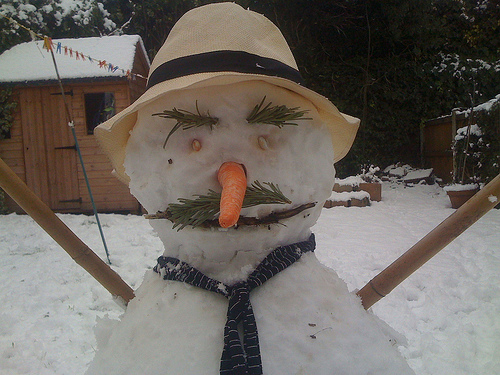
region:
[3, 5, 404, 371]
a snowman wearing a hat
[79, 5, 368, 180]
a beige straw hat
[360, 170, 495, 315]
a stick on right side of snowman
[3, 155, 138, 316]
a stick on left side of snowman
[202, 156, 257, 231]
a carrot forming the nose of snowman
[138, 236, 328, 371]
a black tie of snowman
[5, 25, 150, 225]
a building cover with snow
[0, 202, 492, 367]
a filed covered with snow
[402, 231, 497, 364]
footsteps over the snow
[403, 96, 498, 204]
a fence of wood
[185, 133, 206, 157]
the eye of a snowman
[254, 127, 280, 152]
the eye of a snowman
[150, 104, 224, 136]
the eyebrows of a snowman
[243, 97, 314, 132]
the eyebrows of a snowman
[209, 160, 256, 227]
a carrot nose of a snowman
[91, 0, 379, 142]
the hat of a snowman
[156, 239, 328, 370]
a tie on a snowman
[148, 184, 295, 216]
the mustache of a snowman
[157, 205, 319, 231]
the mouth of a snowman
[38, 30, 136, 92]
the roof of a building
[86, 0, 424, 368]
a snowman in the snow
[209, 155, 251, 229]
a large orange carrot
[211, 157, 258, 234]
the nose of a snowman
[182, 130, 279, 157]
the eyes of a snowman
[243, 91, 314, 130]
the eyebrow of a snowman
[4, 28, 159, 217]
a small wooden shed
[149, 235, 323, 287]
the neck of a snowman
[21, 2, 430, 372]
Close up of a snowman.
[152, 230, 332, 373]
Tie around snowman's neck.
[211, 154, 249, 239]
An orange carrot.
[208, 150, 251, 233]
Nose made of a carrot.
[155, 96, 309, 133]
Eyebrows made of pieces of pine needles.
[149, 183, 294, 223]
Moustache made of pieces of pine needles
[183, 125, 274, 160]
Eyes of the snowman.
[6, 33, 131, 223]
A wood building in the background.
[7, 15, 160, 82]
Snow on roof of building.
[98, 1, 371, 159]
A white hat with a black band.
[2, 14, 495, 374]
A dressed up snowman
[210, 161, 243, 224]
An orange carrot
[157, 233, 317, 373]
A blue tie around the pile of snow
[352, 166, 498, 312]
A wooden pole stuck in the snow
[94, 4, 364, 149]
A soft hat on the snowman's head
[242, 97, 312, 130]
A pine leaf as an eyebrow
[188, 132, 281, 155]
Rocks as the snowman's eyes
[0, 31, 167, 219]
A wooden cabin with snow on the roof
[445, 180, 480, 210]
A snowy flower pot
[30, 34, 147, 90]
Clothespins on a laundry line